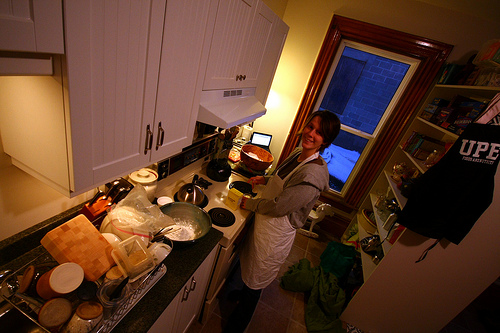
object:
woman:
[223, 110, 342, 332]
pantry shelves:
[367, 192, 390, 256]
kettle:
[174, 179, 204, 204]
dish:
[36, 259, 84, 295]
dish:
[110, 233, 154, 278]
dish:
[36, 296, 71, 326]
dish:
[65, 299, 102, 329]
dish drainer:
[0, 247, 167, 332]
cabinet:
[202, 0, 252, 90]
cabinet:
[68, 0, 153, 192]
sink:
[1, 295, 40, 330]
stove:
[161, 160, 261, 246]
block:
[80, 195, 115, 222]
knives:
[107, 189, 129, 208]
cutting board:
[1, 246, 165, 332]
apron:
[237, 149, 321, 289]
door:
[310, 38, 418, 199]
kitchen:
[0, 0, 499, 332]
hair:
[305, 110, 343, 150]